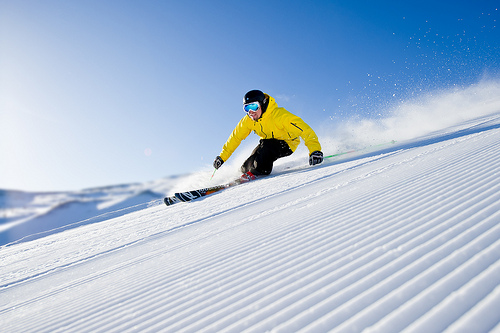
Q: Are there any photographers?
A: No, there are no photographers.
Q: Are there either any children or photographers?
A: No, there are no photographers or children.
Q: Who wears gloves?
A: The guy wears gloves.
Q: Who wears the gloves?
A: The guy wears gloves.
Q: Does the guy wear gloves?
A: Yes, the guy wears gloves.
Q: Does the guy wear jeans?
A: No, the guy wears gloves.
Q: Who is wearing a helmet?
A: The guy is wearing a helmet.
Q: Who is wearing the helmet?
A: The guy is wearing a helmet.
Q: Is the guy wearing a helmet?
A: Yes, the guy is wearing a helmet.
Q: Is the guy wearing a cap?
A: No, the guy is wearing a helmet.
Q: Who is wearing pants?
A: The guy is wearing pants.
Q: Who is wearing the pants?
A: The guy is wearing pants.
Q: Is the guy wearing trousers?
A: Yes, the guy is wearing trousers.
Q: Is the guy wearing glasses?
A: No, the guy is wearing trousers.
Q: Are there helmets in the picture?
A: Yes, there is a helmet.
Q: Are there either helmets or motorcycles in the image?
A: Yes, there is a helmet.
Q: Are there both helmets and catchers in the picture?
A: No, there is a helmet but no catchers.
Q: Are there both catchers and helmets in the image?
A: No, there is a helmet but no catchers.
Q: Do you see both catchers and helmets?
A: No, there is a helmet but no catchers.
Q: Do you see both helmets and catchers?
A: No, there is a helmet but no catchers.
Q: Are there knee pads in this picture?
A: No, there are no knee pads.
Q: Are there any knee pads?
A: No, there are no knee pads.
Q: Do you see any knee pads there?
A: No, there are no knee pads.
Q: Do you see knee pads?
A: No, there are no knee pads.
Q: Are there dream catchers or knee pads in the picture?
A: No, there are no knee pads or dream catchers.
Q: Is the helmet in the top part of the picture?
A: Yes, the helmet is in the top of the image.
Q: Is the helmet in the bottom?
A: No, the helmet is in the top of the image.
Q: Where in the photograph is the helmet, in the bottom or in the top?
A: The helmet is in the top of the image.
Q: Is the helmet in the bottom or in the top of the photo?
A: The helmet is in the top of the image.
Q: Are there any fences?
A: No, there are no fences.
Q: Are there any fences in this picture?
A: No, there are no fences.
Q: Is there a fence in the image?
A: No, there are no fences.